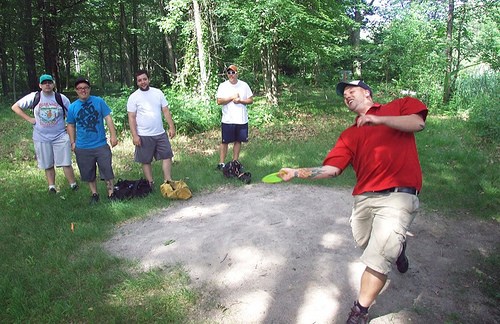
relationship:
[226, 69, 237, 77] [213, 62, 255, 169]
sunglasses on man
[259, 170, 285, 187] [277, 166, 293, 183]
disc in hand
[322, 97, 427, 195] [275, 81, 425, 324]
polo on he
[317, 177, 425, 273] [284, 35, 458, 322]
shorts on man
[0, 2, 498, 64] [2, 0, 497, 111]
green leaves on trees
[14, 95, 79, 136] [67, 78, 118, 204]
shirt on he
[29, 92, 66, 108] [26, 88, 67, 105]
straps over shoulder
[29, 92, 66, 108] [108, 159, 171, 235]
straps of backpack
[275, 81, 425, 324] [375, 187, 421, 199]
he has belt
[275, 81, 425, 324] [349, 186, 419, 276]
he has shorts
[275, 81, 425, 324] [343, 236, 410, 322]
he has shoes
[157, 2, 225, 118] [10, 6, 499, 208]
tree in background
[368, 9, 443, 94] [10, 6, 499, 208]
tree in background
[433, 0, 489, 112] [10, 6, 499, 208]
tree in background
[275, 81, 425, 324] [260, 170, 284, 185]
he throwing frisbee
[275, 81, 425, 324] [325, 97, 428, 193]
he wearing polo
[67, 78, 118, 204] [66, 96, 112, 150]
he wearing shirt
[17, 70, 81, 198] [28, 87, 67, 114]
man wearing backpack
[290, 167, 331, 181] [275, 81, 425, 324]
arm tattoos inked on he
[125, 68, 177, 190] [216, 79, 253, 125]
man wearing shirt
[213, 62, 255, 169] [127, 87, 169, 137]
man wearing shirt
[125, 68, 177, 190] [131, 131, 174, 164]
man wearing shorts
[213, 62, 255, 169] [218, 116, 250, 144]
man wearing shorts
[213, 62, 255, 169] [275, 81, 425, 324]
man watching he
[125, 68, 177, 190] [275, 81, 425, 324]
man watching he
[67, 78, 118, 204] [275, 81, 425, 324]
he watching he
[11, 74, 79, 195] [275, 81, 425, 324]
man watching he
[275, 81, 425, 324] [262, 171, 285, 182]
he throwing disc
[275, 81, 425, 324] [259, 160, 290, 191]
he throwing frisbee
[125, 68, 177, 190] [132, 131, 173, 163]
man has grey shorts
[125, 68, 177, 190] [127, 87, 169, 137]
man has shirt